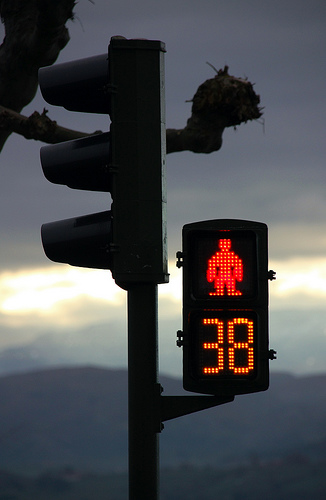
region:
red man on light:
[195, 236, 247, 293]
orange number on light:
[200, 318, 225, 372]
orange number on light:
[224, 316, 257, 371]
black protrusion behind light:
[152, 56, 261, 151]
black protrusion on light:
[157, 382, 225, 414]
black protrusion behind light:
[1, 100, 98, 140]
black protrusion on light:
[37, 51, 110, 108]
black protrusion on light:
[39, 127, 110, 184]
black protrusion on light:
[38, 206, 110, 264]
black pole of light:
[125, 285, 158, 498]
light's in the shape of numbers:
[187, 309, 283, 387]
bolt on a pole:
[150, 376, 170, 399]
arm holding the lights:
[117, 388, 243, 435]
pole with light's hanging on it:
[19, 31, 184, 498]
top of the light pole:
[32, 24, 187, 132]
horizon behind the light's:
[8, 224, 323, 369]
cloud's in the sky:
[5, 248, 319, 364]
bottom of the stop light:
[21, 200, 170, 284]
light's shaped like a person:
[192, 236, 255, 310]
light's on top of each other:
[40, 32, 134, 289]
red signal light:
[188, 226, 281, 407]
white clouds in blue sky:
[264, 145, 292, 165]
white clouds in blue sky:
[277, 260, 317, 303]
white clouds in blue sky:
[283, 300, 315, 327]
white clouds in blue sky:
[278, 129, 304, 185]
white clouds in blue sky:
[58, 330, 96, 351]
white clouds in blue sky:
[10, 312, 43, 334]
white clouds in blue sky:
[42, 281, 101, 327]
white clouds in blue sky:
[5, 264, 69, 320]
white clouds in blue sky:
[183, 164, 219, 189]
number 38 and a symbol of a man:
[176, 215, 271, 391]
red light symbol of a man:
[201, 229, 248, 301]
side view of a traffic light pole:
[37, 33, 172, 497]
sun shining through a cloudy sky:
[0, 248, 325, 314]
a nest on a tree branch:
[188, 61, 259, 135]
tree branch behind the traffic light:
[5, 0, 262, 167]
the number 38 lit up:
[192, 314, 260, 373]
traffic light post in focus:
[37, 34, 270, 498]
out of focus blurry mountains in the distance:
[3, 352, 324, 498]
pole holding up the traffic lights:
[127, 284, 159, 495]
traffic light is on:
[187, 235, 256, 390]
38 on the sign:
[190, 313, 260, 379]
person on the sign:
[174, 224, 251, 302]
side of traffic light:
[3, 62, 162, 283]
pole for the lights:
[112, 362, 161, 486]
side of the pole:
[189, 47, 282, 144]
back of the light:
[125, 142, 171, 276]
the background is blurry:
[223, 434, 256, 473]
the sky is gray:
[259, 40, 272, 47]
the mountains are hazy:
[206, 458, 281, 494]